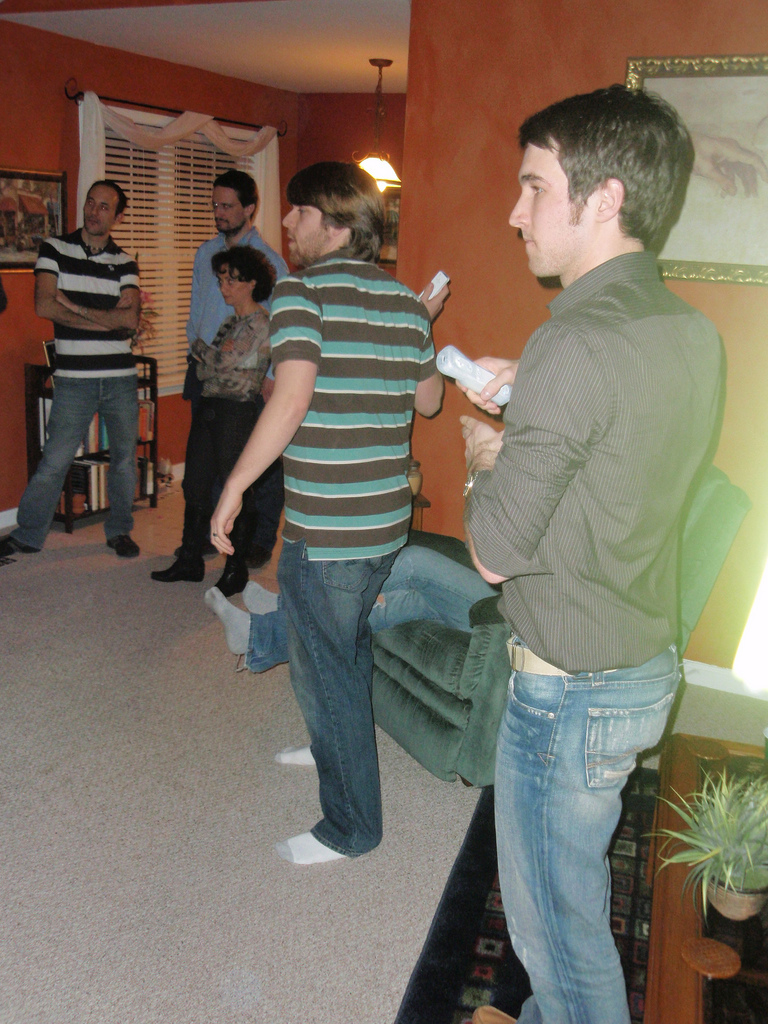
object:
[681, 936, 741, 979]
coaster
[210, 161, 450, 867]
man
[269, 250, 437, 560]
shirt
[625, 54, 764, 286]
frame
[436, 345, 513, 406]
controller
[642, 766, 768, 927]
plant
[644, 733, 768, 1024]
table